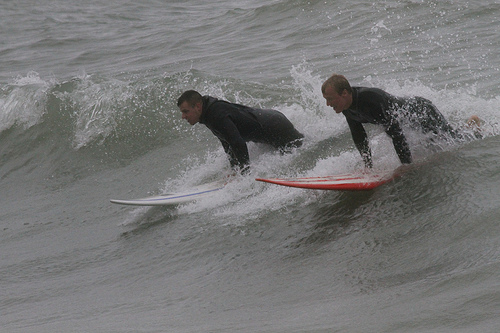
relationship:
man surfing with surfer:
[176, 89, 304, 177] [321, 73, 484, 174]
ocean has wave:
[2, 1, 500, 333] [2, 63, 499, 328]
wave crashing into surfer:
[2, 63, 499, 328] [321, 73, 484, 174]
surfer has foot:
[321, 73, 484, 174] [464, 111, 486, 144]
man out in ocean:
[176, 89, 304, 177] [2, 1, 500, 333]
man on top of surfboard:
[176, 89, 304, 177] [106, 177, 243, 210]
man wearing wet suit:
[176, 89, 304, 177] [200, 92, 304, 172]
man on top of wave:
[176, 89, 304, 177] [2, 63, 499, 328]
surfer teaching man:
[321, 73, 484, 174] [176, 89, 304, 177]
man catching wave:
[176, 89, 304, 177] [2, 63, 499, 328]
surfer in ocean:
[321, 73, 484, 174] [2, 1, 500, 333]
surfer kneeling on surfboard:
[321, 73, 484, 174] [251, 172, 396, 193]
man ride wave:
[176, 89, 304, 177] [2, 63, 499, 328]